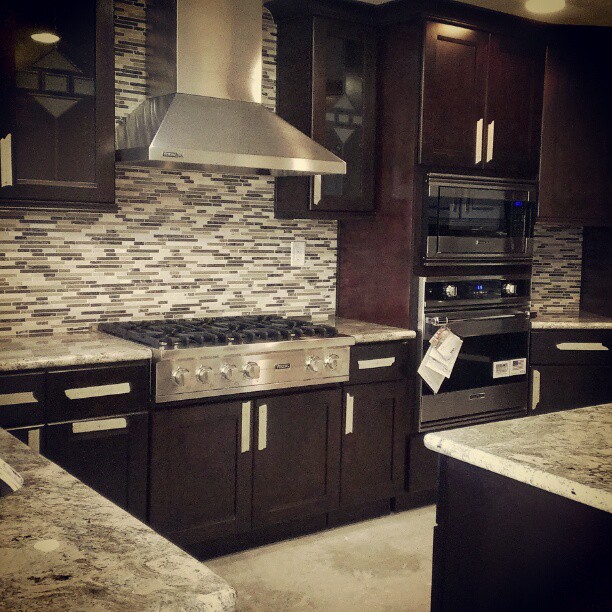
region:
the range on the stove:
[125, 313, 337, 341]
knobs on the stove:
[172, 364, 269, 379]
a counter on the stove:
[10, 325, 150, 357]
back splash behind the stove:
[8, 210, 333, 323]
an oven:
[422, 276, 528, 407]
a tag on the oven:
[410, 329, 462, 389]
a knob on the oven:
[448, 282, 456, 294]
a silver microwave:
[428, 181, 539, 259]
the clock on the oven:
[469, 283, 482, 291]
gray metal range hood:
[111, 2, 348, 176]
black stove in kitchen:
[102, 308, 334, 355]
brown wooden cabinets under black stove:
[0, 345, 403, 568]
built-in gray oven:
[418, 272, 536, 424]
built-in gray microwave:
[429, 169, 539, 263]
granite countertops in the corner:
[412, 399, 609, 509]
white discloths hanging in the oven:
[414, 326, 462, 395]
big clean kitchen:
[0, 8, 608, 598]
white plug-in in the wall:
[287, 240, 304, 271]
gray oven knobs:
[442, 280, 518, 300]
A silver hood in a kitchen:
[115, 2, 345, 182]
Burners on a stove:
[105, 310, 342, 352]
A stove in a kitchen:
[105, 315, 354, 401]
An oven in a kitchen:
[416, 277, 527, 436]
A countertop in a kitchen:
[422, 396, 610, 521]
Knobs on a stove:
[171, 352, 339, 381]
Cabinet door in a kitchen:
[250, 384, 342, 525]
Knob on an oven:
[443, 281, 457, 297]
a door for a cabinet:
[5, 2, 114, 209]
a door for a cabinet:
[168, 403, 248, 556]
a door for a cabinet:
[352, 377, 412, 508]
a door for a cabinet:
[310, 6, 371, 212]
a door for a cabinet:
[426, 11, 486, 170]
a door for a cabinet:
[492, 35, 547, 169]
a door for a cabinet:
[526, 363, 609, 412]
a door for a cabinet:
[545, 44, 591, 231]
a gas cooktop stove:
[103, 308, 364, 405]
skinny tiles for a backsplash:
[125, 173, 275, 316]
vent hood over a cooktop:
[118, 67, 352, 193]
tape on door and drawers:
[6, 383, 147, 439]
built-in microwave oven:
[423, 171, 544, 267]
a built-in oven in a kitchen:
[412, 268, 544, 429]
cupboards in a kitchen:
[64, 373, 434, 520]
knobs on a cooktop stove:
[168, 359, 266, 384]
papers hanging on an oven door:
[417, 317, 472, 399]